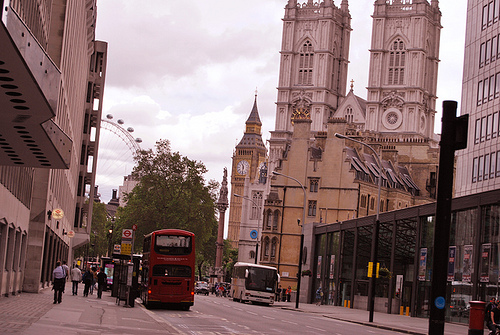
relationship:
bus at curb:
[228, 260, 283, 311] [258, 293, 307, 313]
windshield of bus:
[246, 263, 278, 293] [228, 260, 283, 311]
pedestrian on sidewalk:
[49, 260, 67, 305] [2, 274, 190, 334]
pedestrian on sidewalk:
[95, 265, 109, 299] [2, 274, 190, 334]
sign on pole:
[364, 258, 382, 281] [366, 220, 385, 326]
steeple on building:
[349, 78, 356, 90] [232, 1, 465, 301]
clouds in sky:
[93, 1, 269, 88] [79, 0, 471, 240]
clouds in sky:
[96, 83, 170, 124] [79, 0, 471, 240]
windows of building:
[472, 157, 481, 186] [449, 0, 500, 329]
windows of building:
[473, 116, 482, 148] [449, 0, 500, 329]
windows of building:
[476, 79, 483, 108] [449, 0, 500, 329]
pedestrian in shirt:
[49, 260, 67, 305] [51, 267, 66, 282]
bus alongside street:
[139, 227, 198, 316] [107, 276, 424, 334]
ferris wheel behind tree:
[81, 110, 157, 243] [110, 139, 231, 291]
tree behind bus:
[110, 139, 231, 291] [139, 227, 198, 316]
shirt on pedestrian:
[51, 267, 66, 282] [49, 260, 67, 305]